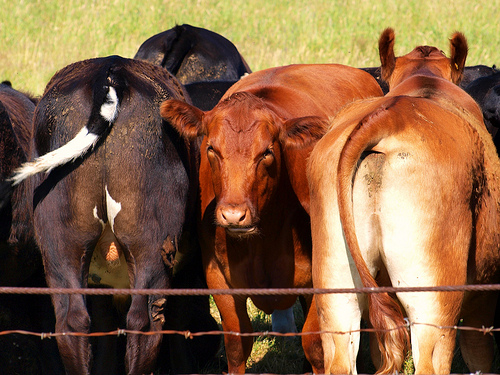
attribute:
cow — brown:
[220, 26, 343, 316]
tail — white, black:
[0, 50, 126, 191]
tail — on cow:
[318, 96, 439, 373]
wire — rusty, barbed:
[1, 322, 498, 347]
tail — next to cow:
[10, 81, 138, 210]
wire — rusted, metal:
[5, 279, 499, 296]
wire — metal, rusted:
[2, 321, 499, 338]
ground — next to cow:
[361, 92, 398, 138]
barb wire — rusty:
[177, 280, 302, 302]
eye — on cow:
[258, 147, 273, 159]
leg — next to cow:
[304, 124, 369, 371]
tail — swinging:
[333, 103, 419, 374]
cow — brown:
[140, 55, 397, 357]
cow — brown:
[161, 50, 498, 364]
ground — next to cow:
[194, 285, 314, 373]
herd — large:
[0, 27, 492, 357]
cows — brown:
[188, 62, 370, 373]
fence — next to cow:
[134, 253, 484, 338]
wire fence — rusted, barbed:
[4, 320, 498, 344]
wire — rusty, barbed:
[116, 250, 399, 360]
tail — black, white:
[23, 108, 126, 163]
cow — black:
[132, 17, 252, 97]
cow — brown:
[298, 22, 498, 373]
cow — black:
[0, 75, 38, 372]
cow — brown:
[157, 62, 385, 372]